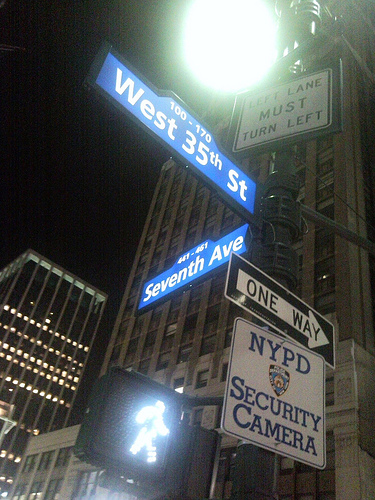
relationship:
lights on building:
[16, 304, 97, 410] [6, 267, 106, 430]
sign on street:
[74, 365, 189, 491] [83, 40, 263, 316]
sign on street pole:
[220, 315, 327, 470] [70, 0, 374, 499]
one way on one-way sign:
[238, 267, 322, 344] [222, 250, 338, 370]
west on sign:
[81, 30, 257, 212] [84, 40, 259, 217]